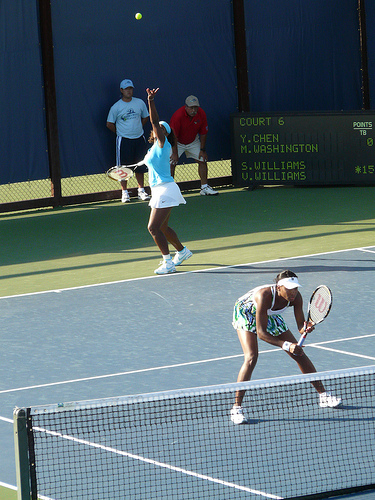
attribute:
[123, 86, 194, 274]
tennis player — female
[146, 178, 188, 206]
skirt — white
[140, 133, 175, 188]
shirt — blue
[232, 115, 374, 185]
display — digital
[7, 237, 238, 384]
tennis court — grey, green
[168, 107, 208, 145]
shirt — red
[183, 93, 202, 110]
cap — white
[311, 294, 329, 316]
logo — wilson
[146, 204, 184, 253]
legs — bare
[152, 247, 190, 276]
shoes — white